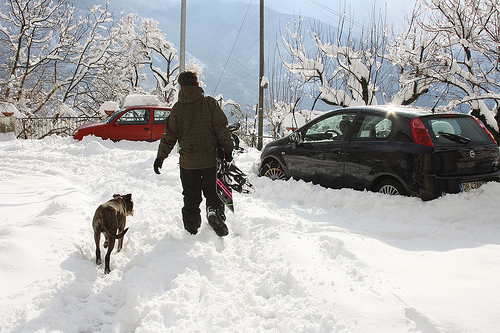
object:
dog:
[92, 193, 134, 274]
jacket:
[157, 84, 235, 170]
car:
[257, 86, 500, 201]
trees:
[374, 0, 499, 146]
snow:
[348, 58, 374, 105]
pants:
[179, 166, 226, 233]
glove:
[152, 155, 168, 174]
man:
[153, 70, 235, 237]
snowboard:
[214, 151, 257, 215]